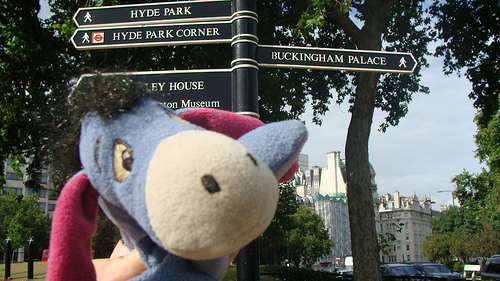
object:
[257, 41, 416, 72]
sign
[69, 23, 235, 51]
sign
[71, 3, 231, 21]
sign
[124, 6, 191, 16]
hyde park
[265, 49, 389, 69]
"buckingham palace"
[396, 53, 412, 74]
emblem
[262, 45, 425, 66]
emblem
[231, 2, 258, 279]
black pole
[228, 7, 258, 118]
stripes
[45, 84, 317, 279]
doll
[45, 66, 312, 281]
toy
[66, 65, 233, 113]
street sign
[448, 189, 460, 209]
streetlight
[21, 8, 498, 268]
england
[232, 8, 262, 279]
pole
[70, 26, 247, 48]
street sign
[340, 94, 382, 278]
tree trunk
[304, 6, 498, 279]
tree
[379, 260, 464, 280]
car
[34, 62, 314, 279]
pooh corner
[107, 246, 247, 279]
hand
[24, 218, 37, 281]
poles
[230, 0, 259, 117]
pole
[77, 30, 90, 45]
person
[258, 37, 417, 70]
street sign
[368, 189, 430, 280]
building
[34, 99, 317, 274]
animal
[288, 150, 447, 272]
view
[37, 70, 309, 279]
eeyore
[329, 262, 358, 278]
cars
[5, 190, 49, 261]
tree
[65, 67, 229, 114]
sign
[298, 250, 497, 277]
park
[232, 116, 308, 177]
ears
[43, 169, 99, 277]
ears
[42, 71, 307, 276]
stuff animal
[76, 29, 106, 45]
emblem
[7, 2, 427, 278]
trees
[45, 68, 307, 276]
puppet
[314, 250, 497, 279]
street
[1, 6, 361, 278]
park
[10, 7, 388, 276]
hyde park